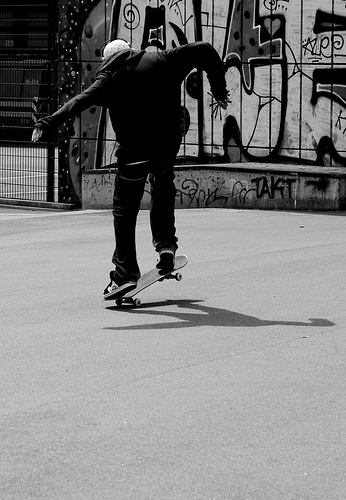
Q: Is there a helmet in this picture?
A: No, there are no helmets.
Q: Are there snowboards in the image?
A: No, there are no snowboards.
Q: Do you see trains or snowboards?
A: No, there are no snowboards or trains.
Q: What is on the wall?
A: The graffiti is on the wall.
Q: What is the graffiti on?
A: The graffiti is on the wall.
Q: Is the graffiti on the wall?
A: Yes, the graffiti is on the wall.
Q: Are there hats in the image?
A: Yes, there is a hat.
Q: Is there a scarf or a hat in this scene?
A: Yes, there is a hat.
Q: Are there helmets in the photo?
A: No, there are no helmets.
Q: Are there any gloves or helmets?
A: No, there are no helmets or gloves.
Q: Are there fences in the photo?
A: Yes, there is a fence.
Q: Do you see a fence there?
A: Yes, there is a fence.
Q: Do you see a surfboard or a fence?
A: Yes, there is a fence.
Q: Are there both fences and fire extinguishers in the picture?
A: No, there is a fence but no fire extinguishers.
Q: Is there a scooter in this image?
A: No, there are no scooters.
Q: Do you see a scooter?
A: No, there are no scooters.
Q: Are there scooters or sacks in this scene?
A: No, there are no scooters or sacks.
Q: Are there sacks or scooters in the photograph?
A: No, there are no scooters or sacks.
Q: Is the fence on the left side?
A: Yes, the fence is on the left of the image.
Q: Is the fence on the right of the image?
A: No, the fence is on the left of the image.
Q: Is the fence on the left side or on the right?
A: The fence is on the left of the image.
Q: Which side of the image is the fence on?
A: The fence is on the left of the image.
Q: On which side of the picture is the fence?
A: The fence is on the left of the image.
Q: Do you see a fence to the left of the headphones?
A: Yes, there is a fence to the left of the headphones.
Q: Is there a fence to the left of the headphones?
A: Yes, there is a fence to the left of the headphones.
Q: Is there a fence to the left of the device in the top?
A: Yes, there is a fence to the left of the headphones.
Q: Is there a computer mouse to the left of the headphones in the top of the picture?
A: No, there is a fence to the left of the headphones.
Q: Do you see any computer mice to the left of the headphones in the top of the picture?
A: No, there is a fence to the left of the headphones.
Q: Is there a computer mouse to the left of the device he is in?
A: No, there is a fence to the left of the headphones.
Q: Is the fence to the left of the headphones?
A: Yes, the fence is to the left of the headphones.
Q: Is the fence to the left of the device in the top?
A: Yes, the fence is to the left of the headphones.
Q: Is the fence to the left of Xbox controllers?
A: No, the fence is to the left of the headphones.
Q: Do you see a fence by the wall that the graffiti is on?
A: Yes, there is a fence by the wall.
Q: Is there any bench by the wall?
A: No, there is a fence by the wall.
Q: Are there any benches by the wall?
A: No, there is a fence by the wall.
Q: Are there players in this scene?
A: No, there are no players.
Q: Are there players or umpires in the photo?
A: No, there are no players or umpires.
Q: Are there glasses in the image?
A: No, there are no glasses.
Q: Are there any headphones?
A: Yes, there are headphones.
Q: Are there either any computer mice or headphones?
A: Yes, there are headphones.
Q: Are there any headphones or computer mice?
A: Yes, there are headphones.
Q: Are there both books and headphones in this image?
A: No, there are headphones but no books.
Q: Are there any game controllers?
A: No, there are no game controllers.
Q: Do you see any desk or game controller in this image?
A: No, there are no game controllers or desks.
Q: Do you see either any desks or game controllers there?
A: No, there are no game controllers or desks.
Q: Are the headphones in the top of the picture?
A: Yes, the headphones are in the top of the image.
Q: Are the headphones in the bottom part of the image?
A: No, the headphones are in the top of the image.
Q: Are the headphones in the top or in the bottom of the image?
A: The headphones are in the top of the image.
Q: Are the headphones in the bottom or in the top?
A: The headphones are in the top of the image.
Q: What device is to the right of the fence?
A: The device is headphones.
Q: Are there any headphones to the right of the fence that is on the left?
A: Yes, there are headphones to the right of the fence.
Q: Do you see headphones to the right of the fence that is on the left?
A: Yes, there are headphones to the right of the fence.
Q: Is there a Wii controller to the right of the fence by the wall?
A: No, there are headphones to the right of the fence.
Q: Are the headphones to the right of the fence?
A: Yes, the headphones are to the right of the fence.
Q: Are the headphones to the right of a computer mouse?
A: No, the headphones are to the right of the fence.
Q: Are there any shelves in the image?
A: No, there are no shelves.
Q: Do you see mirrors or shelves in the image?
A: No, there are no shelves or mirrors.